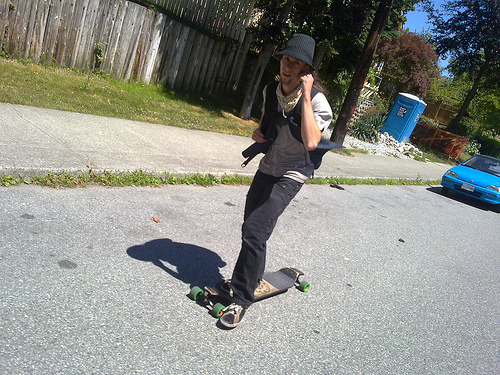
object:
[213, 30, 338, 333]
man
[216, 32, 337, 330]
skater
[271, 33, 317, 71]
fedora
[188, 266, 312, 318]
skateboard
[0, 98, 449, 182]
sidewalk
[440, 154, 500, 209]
car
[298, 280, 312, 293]
wheel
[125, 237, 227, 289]
shadow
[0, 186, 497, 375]
pavement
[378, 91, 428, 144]
port a potty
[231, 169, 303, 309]
jeans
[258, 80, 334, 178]
vest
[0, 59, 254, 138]
grass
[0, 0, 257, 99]
fence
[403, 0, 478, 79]
sky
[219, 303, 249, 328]
shoe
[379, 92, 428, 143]
trash bag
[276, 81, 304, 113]
scarf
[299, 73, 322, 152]
arm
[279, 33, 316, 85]
head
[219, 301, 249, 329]
foot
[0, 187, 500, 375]
ground